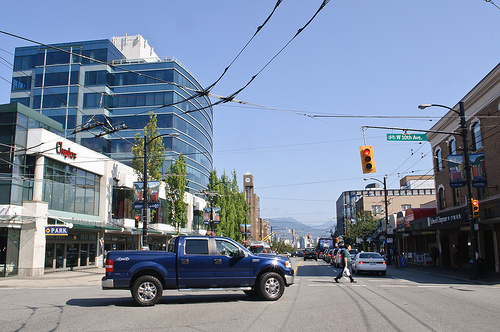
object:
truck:
[100, 234, 297, 308]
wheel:
[258, 271, 285, 301]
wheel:
[131, 275, 164, 307]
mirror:
[232, 246, 244, 259]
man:
[331, 243, 356, 287]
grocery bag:
[342, 266, 351, 277]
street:
[0, 249, 495, 331]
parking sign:
[44, 225, 69, 237]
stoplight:
[362, 146, 373, 171]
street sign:
[388, 133, 430, 142]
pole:
[361, 124, 465, 134]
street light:
[416, 102, 433, 110]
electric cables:
[52, 48, 325, 139]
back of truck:
[103, 234, 295, 305]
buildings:
[330, 63, 500, 273]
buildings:
[0, 35, 267, 274]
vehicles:
[295, 237, 387, 277]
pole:
[459, 101, 484, 279]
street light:
[471, 200, 480, 218]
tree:
[166, 153, 189, 241]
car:
[349, 251, 387, 276]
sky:
[0, 0, 498, 135]